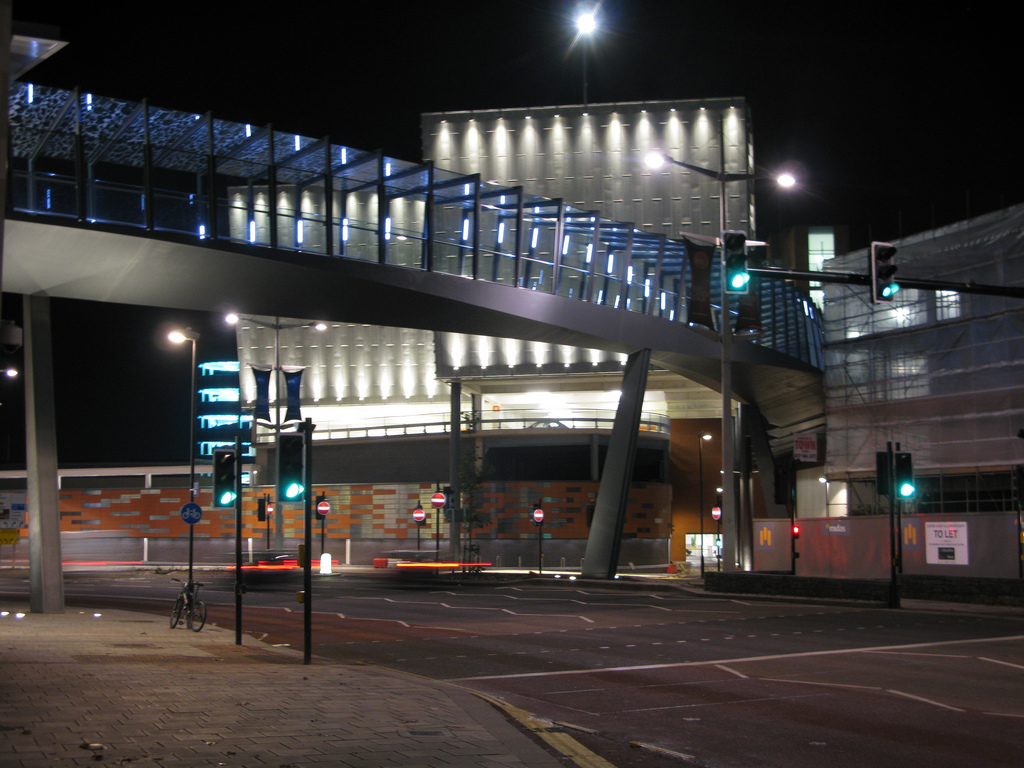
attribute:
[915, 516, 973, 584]
poster — white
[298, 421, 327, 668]
pole — black, metal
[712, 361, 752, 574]
column — large, grey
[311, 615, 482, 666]
lane — large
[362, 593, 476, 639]
lane — large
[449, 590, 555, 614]
lane — large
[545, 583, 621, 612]
lane — large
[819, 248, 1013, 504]
buildings — large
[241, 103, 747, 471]
buildings — large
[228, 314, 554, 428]
buildings — large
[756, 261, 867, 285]
pole — green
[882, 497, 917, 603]
pole — green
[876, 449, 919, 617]
signal — electric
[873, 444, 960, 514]
traffic signal — electric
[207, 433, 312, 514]
signal — electric